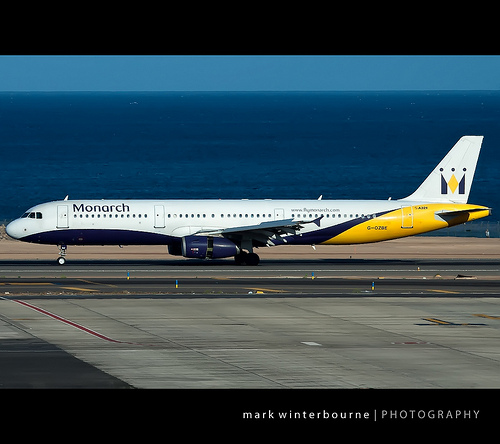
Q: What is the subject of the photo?
A: Plane.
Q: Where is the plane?
A: Runway.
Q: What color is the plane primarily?
A: White.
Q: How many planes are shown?
A: One.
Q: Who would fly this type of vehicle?
A: Pilot.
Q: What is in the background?
A: Ocean.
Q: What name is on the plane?
A: Monarch.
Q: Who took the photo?
A: Mark Winterbourne.